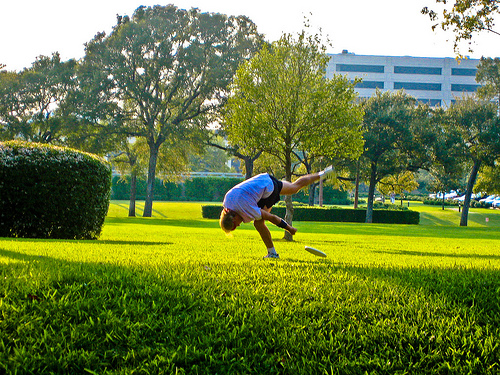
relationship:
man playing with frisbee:
[218, 161, 339, 261] [304, 243, 329, 262]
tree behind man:
[223, 12, 367, 241] [218, 161, 339, 261]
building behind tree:
[318, 49, 499, 189] [223, 12, 367, 241]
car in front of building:
[476, 192, 499, 207] [318, 49, 499, 189]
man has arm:
[218, 161, 339, 261] [244, 202, 298, 238]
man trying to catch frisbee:
[218, 161, 339, 261] [304, 243, 329, 262]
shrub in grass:
[1, 137, 115, 248] [0, 199, 499, 272]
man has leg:
[218, 161, 339, 261] [272, 160, 337, 197]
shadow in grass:
[93, 234, 178, 254] [0, 199, 499, 272]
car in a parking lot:
[476, 192, 499, 207] [428, 184, 500, 210]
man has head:
[218, 161, 339, 261] [216, 207, 244, 236]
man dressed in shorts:
[218, 161, 339, 261] [259, 166, 284, 210]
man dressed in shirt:
[218, 161, 339, 261] [221, 173, 275, 223]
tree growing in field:
[223, 12, 367, 241] [0, 202, 498, 374]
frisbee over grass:
[304, 243, 329, 262] [0, 199, 499, 272]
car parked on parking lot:
[476, 192, 499, 207] [428, 184, 500, 210]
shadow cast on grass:
[93, 234, 178, 254] [0, 199, 499, 272]